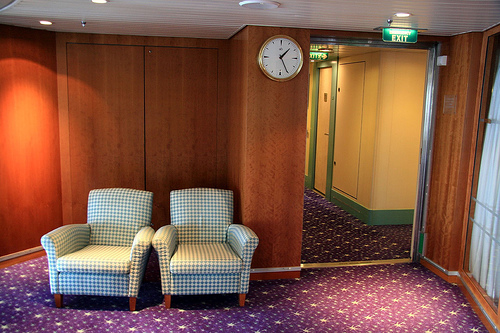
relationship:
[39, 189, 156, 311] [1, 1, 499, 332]
chair in room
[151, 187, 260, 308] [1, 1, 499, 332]
chair in room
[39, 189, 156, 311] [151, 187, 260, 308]
chair by chair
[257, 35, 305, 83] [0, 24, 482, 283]
clock on walls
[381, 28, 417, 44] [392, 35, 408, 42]
sign says exit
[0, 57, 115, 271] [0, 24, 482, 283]
light on walls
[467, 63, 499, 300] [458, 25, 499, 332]
curtain in window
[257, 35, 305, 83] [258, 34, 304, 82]
clock has trim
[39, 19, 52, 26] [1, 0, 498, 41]
light on ceiling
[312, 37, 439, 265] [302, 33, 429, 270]
moulding in doorway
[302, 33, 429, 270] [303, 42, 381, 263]
doorway to hall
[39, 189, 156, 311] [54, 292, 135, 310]
chair has legs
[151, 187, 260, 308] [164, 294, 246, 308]
chair has legs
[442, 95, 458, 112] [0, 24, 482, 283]
plate on walls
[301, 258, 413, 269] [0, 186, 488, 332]
trim on floor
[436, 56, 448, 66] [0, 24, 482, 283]
box on walls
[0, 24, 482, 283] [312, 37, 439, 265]
walls have moulding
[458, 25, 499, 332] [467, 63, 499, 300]
window with curtain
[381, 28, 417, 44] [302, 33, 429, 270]
sign above doorway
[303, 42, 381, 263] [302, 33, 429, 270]
hall through doorway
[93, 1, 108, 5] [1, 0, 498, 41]
light on ceiling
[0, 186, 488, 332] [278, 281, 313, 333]
floor has stars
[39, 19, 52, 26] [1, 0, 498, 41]
light in ceiling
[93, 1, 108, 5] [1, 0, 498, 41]
light in ceiling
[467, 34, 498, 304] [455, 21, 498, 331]
glass in door